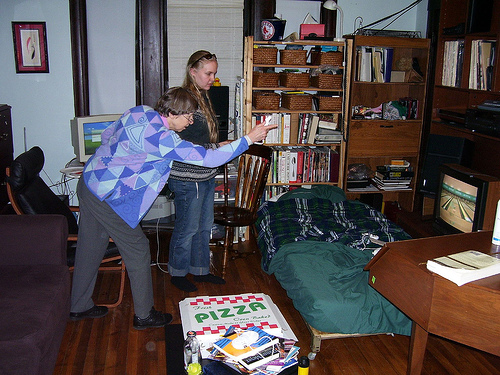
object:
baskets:
[254, 46, 278, 64]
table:
[364, 230, 499, 373]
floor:
[54, 206, 499, 375]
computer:
[433, 168, 500, 233]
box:
[176, 293, 300, 343]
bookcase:
[240, 35, 346, 193]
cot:
[277, 184, 381, 333]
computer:
[69, 113, 119, 163]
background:
[0, 1, 151, 166]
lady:
[61, 89, 281, 327]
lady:
[156, 51, 228, 291]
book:
[425, 250, 498, 287]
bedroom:
[0, 0, 500, 375]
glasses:
[172, 112, 206, 122]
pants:
[68, 179, 176, 313]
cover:
[253, 240, 414, 335]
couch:
[0, 210, 81, 375]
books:
[304, 115, 318, 144]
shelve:
[337, 38, 421, 218]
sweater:
[83, 105, 248, 230]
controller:
[250, 108, 284, 142]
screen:
[438, 174, 477, 233]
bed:
[255, 185, 418, 355]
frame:
[8, 21, 49, 75]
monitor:
[80, 119, 136, 155]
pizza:
[194, 302, 266, 324]